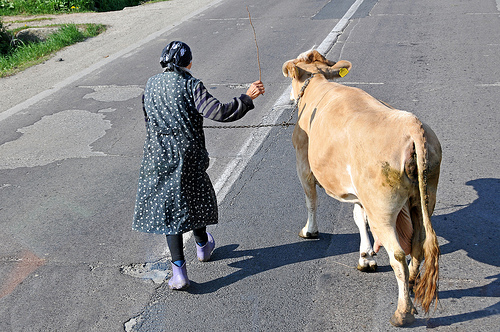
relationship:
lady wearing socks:
[131, 40, 266, 291] [166, 235, 204, 257]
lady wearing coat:
[131, 40, 266, 291] [132, 66, 256, 235]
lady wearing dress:
[131, 40, 266, 291] [130, 67, 220, 233]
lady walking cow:
[131, 40, 266, 291] [282, 49, 444, 327]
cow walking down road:
[274, 39, 454, 329] [6, 0, 500, 332]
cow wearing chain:
[282, 49, 444, 327] [201, 72, 323, 130]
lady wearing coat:
[131, 40, 266, 291] [141, 67, 249, 225]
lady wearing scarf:
[131, 40, 266, 291] [155, 39, 193, 69]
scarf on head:
[155, 39, 193, 69] [158, 40, 197, 69]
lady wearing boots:
[131, 40, 266, 291] [165, 232, 215, 290]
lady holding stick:
[131, 40, 266, 291] [244, 3, 263, 80]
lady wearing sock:
[131, 40, 266, 291] [173, 259, 183, 264]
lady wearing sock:
[131, 40, 266, 291] [197, 241, 206, 244]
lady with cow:
[131, 40, 266, 291] [282, 49, 444, 327]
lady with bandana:
[131, 40, 266, 291] [154, 40, 195, 72]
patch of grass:
[2, 2, 144, 77] [2, 0, 144, 75]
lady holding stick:
[131, 40, 266, 291] [245, 7, 264, 83]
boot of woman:
[168, 259, 190, 290] [141, 37, 221, 281]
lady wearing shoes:
[131, 40, 266, 291] [165, 235, 233, 296]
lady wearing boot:
[131, 40, 266, 291] [194, 232, 215, 261]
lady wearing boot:
[131, 40, 266, 291] [168, 259, 190, 290]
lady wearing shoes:
[131, 40, 266, 291] [165, 232, 215, 289]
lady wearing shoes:
[131, 40, 266, 291] [160, 227, 212, 299]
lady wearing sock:
[131, 40, 266, 291] [174, 259, 181, 266]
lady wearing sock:
[131, 40, 266, 291] [197, 241, 207, 245]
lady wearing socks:
[131, 40, 266, 291] [170, 240, 214, 270]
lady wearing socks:
[131, 40, 266, 291] [141, 223, 261, 288]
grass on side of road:
[7, 1, 102, 96] [6, 0, 484, 330]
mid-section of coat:
[148, 120, 202, 148] [132, 66, 256, 235]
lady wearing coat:
[100, 24, 274, 299] [132, 66, 256, 235]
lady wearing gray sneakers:
[131, 40, 266, 291] [154, 241, 223, 288]